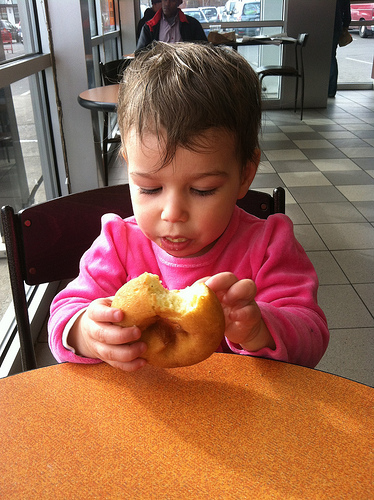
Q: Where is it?
A: This is at the restaurant.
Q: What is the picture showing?
A: It is showing a restaurant.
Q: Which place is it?
A: It is a restaurant.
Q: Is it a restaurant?
A: Yes, it is a restaurant.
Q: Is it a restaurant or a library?
A: It is a restaurant.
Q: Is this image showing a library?
A: No, the picture is showing a restaurant.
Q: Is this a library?
A: No, it is a restaurant.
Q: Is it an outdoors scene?
A: Yes, it is outdoors.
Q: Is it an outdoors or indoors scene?
A: It is outdoors.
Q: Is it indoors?
A: No, it is outdoors.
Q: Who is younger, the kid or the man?
A: The kid is younger than the man.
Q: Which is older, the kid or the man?
A: The man is older than the kid.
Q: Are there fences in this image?
A: No, there are no fences.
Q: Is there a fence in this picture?
A: No, there are no fences.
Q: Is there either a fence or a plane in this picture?
A: No, there are no fences or airplanes.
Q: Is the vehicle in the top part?
A: Yes, the vehicle is in the top of the image.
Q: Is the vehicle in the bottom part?
A: No, the vehicle is in the top of the image.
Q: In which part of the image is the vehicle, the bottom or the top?
A: The vehicle is in the top of the image.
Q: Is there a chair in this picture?
A: Yes, there is a chair.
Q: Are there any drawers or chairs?
A: Yes, there is a chair.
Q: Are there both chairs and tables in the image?
A: Yes, there are both a chair and a table.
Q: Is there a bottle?
A: No, there are no bottles.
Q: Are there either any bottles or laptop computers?
A: No, there are no bottles or laptop computers.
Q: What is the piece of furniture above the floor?
A: The piece of furniture is a chair.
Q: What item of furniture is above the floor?
A: The piece of furniture is a chair.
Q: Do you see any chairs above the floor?
A: Yes, there is a chair above the floor.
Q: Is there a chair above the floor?
A: Yes, there is a chair above the floor.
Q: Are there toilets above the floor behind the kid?
A: No, there is a chair above the floor.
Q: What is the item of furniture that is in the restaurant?
A: The piece of furniture is a chair.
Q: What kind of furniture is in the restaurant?
A: The piece of furniture is a chair.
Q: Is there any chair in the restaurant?
A: Yes, there is a chair in the restaurant.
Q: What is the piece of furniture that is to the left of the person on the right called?
A: The piece of furniture is a chair.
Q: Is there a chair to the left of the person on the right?
A: Yes, there is a chair to the left of the person.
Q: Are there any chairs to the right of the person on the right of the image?
A: No, the chair is to the left of the person.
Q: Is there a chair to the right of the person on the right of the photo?
A: No, the chair is to the left of the person.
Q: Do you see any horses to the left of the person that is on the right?
A: No, there is a chair to the left of the person.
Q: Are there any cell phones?
A: No, there are no cell phones.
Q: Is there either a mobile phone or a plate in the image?
A: No, there are no cell phones or plates.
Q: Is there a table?
A: Yes, there is a table.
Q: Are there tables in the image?
A: Yes, there is a table.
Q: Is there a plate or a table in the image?
A: Yes, there is a table.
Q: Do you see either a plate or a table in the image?
A: Yes, there is a table.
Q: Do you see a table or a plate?
A: Yes, there is a table.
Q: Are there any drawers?
A: No, there are no drawers.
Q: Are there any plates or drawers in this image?
A: No, there are no drawers or plates.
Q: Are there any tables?
A: Yes, there is a table.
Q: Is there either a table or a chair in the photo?
A: Yes, there is a table.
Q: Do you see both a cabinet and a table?
A: No, there is a table but no cabinets.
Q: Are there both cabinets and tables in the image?
A: No, there is a table but no cabinets.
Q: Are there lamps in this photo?
A: No, there are no lamps.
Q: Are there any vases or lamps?
A: No, there are no lamps or vases.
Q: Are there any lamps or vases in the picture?
A: No, there are no lamps or vases.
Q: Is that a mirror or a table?
A: That is a table.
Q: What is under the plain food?
A: The table is under the donut.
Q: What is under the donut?
A: The table is under the donut.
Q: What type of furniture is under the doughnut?
A: The piece of furniture is a table.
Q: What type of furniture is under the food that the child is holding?
A: The piece of furniture is a table.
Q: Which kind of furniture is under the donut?
A: The piece of furniture is a table.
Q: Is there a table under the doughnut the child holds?
A: Yes, there is a table under the donut.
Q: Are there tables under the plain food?
A: Yes, there is a table under the donut.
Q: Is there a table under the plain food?
A: Yes, there is a table under the donut.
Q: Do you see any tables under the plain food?
A: Yes, there is a table under the donut.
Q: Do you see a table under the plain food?
A: Yes, there is a table under the donut.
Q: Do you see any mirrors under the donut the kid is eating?
A: No, there is a table under the doughnut.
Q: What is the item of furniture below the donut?
A: The piece of furniture is a table.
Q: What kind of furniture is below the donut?
A: The piece of furniture is a table.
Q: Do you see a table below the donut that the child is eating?
A: Yes, there is a table below the donut.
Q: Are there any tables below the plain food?
A: Yes, there is a table below the donut.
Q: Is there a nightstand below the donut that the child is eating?
A: No, there is a table below the doughnut.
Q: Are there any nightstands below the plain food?
A: No, there is a table below the doughnut.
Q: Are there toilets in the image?
A: No, there are no toilets.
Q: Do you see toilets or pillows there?
A: No, there are no toilets or pillows.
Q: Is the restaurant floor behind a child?
A: Yes, the floor is behind a child.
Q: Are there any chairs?
A: Yes, there is a chair.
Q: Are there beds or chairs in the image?
A: Yes, there is a chair.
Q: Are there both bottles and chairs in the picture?
A: No, there is a chair but no bottles.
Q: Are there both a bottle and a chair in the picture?
A: No, there is a chair but no bottles.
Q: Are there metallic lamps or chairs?
A: Yes, there is a metal chair.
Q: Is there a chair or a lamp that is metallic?
A: Yes, the chair is metallic.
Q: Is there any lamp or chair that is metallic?
A: Yes, the chair is metallic.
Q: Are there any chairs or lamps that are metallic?
A: Yes, the chair is metallic.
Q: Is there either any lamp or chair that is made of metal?
A: Yes, the chair is made of metal.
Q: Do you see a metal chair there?
A: Yes, there is a metal chair.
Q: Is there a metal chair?
A: Yes, there is a metal chair.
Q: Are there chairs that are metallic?
A: Yes, there is a chair that is metallic.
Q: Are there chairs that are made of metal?
A: Yes, there is a chair that is made of metal.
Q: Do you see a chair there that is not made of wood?
A: Yes, there is a chair that is made of metal.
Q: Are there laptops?
A: No, there are no laptops.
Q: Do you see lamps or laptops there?
A: No, there are no laptops or lamps.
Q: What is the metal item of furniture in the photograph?
A: The piece of furniture is a chair.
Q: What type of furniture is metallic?
A: The furniture is a chair.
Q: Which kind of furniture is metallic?
A: The furniture is a chair.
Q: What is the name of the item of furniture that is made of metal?
A: The piece of furniture is a chair.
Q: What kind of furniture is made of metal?
A: The furniture is a chair.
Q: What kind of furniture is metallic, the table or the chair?
A: The chair is metallic.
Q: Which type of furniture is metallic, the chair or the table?
A: The chair is metallic.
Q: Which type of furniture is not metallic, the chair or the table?
A: The table is not metallic.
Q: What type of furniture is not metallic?
A: The furniture is a table.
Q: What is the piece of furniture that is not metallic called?
A: The piece of furniture is a table.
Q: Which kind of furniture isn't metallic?
A: The furniture is a table.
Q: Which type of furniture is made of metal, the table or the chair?
A: The chair is made of metal.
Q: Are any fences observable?
A: No, there are no fences.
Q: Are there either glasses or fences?
A: No, there are no fences or glasses.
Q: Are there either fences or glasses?
A: No, there are no fences or glasses.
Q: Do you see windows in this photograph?
A: Yes, there is a window.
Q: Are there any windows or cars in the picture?
A: Yes, there is a window.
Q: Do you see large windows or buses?
A: Yes, there is a large window.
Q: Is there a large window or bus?
A: Yes, there is a large window.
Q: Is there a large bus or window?
A: Yes, there is a large window.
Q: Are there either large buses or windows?
A: Yes, there is a large window.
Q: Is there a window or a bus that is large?
A: Yes, the window is large.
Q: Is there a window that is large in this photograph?
A: Yes, there is a large window.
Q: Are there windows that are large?
A: Yes, there is a window that is large.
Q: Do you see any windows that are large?
A: Yes, there is a window that is large.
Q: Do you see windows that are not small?
A: Yes, there is a large window.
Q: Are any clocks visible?
A: No, there are no clocks.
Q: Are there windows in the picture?
A: Yes, there is a window.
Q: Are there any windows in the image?
A: Yes, there is a window.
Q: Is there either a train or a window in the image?
A: Yes, there is a window.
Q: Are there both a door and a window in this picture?
A: Yes, there are both a window and a door.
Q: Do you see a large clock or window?
A: Yes, there is a large window.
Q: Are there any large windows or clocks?
A: Yes, there is a large window.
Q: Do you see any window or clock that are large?
A: Yes, the window is large.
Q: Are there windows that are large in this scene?
A: Yes, there is a large window.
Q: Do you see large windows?
A: Yes, there is a large window.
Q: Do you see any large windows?
A: Yes, there is a large window.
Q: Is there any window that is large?
A: Yes, there is a window that is large.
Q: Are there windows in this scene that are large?
A: Yes, there is a window that is large.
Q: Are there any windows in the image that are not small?
A: Yes, there is a large window.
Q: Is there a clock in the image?
A: No, there are no clocks.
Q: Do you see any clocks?
A: No, there are no clocks.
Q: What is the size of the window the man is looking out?
A: The window is large.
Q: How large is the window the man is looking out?
A: The window is large.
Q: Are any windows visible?
A: Yes, there is a window.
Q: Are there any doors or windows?
A: Yes, there is a window.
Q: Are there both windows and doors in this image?
A: Yes, there are both a window and a door.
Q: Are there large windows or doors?
A: Yes, there is a large window.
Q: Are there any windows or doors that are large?
A: Yes, the window is large.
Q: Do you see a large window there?
A: Yes, there is a large window.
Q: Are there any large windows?
A: Yes, there is a large window.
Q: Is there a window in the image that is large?
A: Yes, there is a window that is large.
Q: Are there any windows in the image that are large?
A: Yes, there is a window that is large.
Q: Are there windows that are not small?
A: Yes, there is a large window.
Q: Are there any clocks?
A: No, there are no clocks.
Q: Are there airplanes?
A: No, there are no airplanes.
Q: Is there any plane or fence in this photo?
A: No, there are no airplanes or fences.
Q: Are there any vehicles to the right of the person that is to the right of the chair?
A: Yes, there is a vehicle to the right of the person.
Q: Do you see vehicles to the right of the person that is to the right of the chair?
A: Yes, there is a vehicle to the right of the person.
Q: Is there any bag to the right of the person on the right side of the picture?
A: No, there is a vehicle to the right of the person.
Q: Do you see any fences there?
A: No, there are no fences.